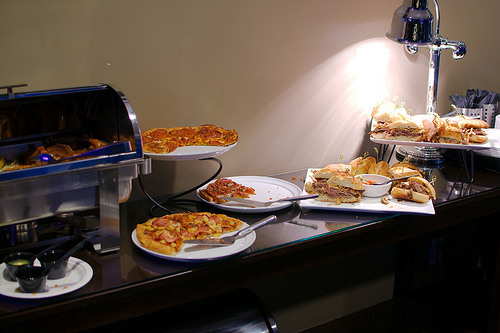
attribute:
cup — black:
[16, 265, 52, 295]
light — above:
[397, 1, 467, 173]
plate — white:
[194, 172, 303, 213]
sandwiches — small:
[314, 156, 434, 203]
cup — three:
[3, 249, 35, 284]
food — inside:
[0, 132, 112, 174]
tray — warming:
[0, 81, 152, 253]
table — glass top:
[0, 167, 498, 331]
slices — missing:
[136, 116, 248, 164]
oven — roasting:
[0, 84, 152, 259]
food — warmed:
[135, 215, 245, 255]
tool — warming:
[0, 74, 155, 263]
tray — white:
[196, 172, 302, 212]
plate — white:
[131, 220, 257, 260]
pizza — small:
[133, 210, 242, 249]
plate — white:
[9, 260, 96, 301]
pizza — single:
[197, 177, 258, 204]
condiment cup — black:
[31, 247, 76, 283]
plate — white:
[0, 251, 98, 301]